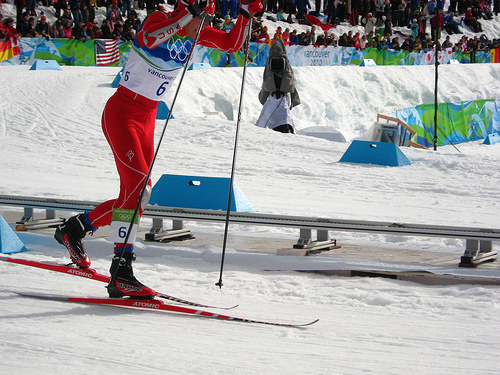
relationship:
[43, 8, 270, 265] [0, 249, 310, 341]
man using skis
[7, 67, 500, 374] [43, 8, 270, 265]
snow under man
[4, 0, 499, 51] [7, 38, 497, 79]
crowd behind wall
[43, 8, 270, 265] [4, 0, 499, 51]
man in front of crowd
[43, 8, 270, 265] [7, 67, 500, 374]
man on snow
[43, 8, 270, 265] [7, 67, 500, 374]
man above snow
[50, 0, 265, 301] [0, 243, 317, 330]
man on skis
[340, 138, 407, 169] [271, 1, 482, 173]
block in background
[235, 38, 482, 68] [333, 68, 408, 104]
railing just above snow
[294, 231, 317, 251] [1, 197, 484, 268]
support of track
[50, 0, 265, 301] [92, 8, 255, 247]
man wearing suit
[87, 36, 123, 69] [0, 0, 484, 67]
flag in background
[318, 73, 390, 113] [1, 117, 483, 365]
snow covering ground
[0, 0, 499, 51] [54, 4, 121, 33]
crowd of people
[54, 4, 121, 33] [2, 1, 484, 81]
people in background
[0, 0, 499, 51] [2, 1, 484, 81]
crowd in background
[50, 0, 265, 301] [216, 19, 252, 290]
man holding pole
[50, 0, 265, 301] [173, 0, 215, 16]
man wearing helmet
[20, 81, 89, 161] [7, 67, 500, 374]
tracks in snow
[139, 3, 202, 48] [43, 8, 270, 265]
arm of a man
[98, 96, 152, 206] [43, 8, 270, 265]
leg of a man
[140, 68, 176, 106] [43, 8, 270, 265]
card on man